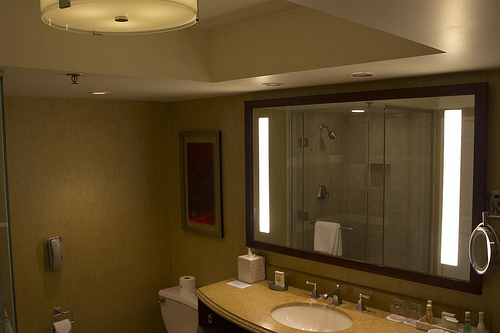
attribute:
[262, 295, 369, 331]
sink — white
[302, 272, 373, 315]
faucet — silver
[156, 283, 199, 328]
toilet — white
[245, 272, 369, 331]
sink — light brown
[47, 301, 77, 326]
holder — silver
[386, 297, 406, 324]
cup — glass 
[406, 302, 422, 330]
cup — glass 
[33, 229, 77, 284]
phone — beige , landline 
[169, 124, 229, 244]
picture — silver , framed 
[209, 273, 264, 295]
rd — white 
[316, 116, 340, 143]
nozzle — silver 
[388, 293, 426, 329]
glasses — empty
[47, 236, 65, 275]
phone — landline 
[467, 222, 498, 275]
mirror — small , round 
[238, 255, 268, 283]
box — white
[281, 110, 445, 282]
glass doors — Glass 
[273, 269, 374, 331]
sink fixtures — silver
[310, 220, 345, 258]
towel — white , hanging up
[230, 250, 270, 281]
roll — toilet paper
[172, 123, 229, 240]
painting — framed 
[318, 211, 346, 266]
towel — white, folded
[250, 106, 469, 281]
mirror — round 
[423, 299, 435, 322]
bottle — yellow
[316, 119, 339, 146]
showerhead — silver 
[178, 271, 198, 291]
toilet paper — rolled